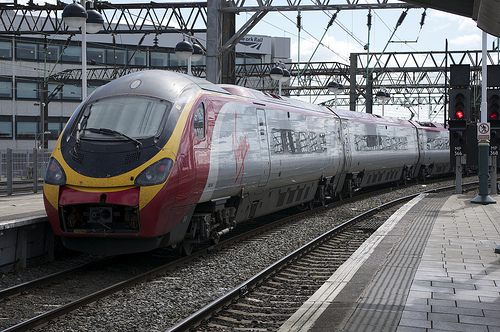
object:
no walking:
[477, 122, 491, 141]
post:
[473, 35, 493, 199]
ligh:
[446, 64, 471, 133]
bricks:
[432, 305, 485, 318]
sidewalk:
[273, 192, 500, 332]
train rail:
[0, 247, 202, 331]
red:
[237, 142, 247, 157]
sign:
[226, 110, 254, 191]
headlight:
[131, 157, 171, 187]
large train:
[41, 69, 451, 255]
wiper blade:
[71, 103, 93, 154]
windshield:
[71, 92, 173, 141]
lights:
[57, 1, 91, 31]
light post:
[75, 6, 93, 116]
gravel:
[124, 275, 176, 317]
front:
[30, 69, 186, 243]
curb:
[275, 188, 426, 332]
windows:
[35, 44, 60, 60]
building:
[0, 4, 291, 182]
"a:
[486, 66, 500, 195]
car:
[325, 104, 419, 193]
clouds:
[294, 36, 341, 63]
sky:
[0, 0, 485, 68]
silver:
[292, 165, 319, 174]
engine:
[41, 71, 346, 256]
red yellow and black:
[82, 126, 203, 219]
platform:
[0, 188, 500, 332]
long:
[273, 131, 328, 154]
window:
[298, 132, 309, 153]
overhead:
[262, 17, 352, 63]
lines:
[323, 10, 371, 53]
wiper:
[80, 126, 143, 148]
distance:
[0, 0, 449, 78]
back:
[418, 121, 450, 177]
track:
[171, 180, 499, 332]